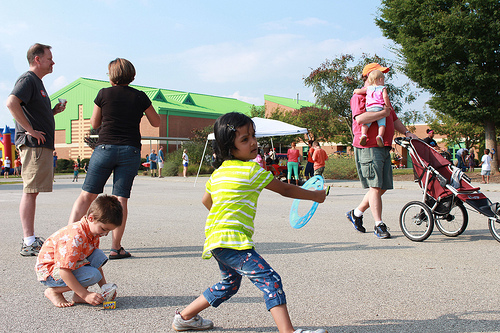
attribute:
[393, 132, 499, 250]
stroller — red, empty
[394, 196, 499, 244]
3 wheels — large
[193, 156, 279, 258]
shirt — white, green, striped, yellow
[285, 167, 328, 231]
frisbee — blue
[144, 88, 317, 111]
roof — lime green, green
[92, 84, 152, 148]
shirt — black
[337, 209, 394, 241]
shoes — black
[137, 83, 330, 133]
building — large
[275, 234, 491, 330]
shadows — of people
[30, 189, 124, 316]
child — kneeling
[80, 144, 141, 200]
shorts — tight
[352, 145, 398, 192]
pants — green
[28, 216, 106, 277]
shirt — orange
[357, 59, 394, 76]
cap — orange